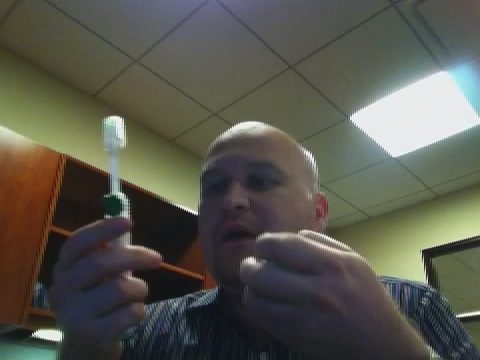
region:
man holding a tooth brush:
[96, 113, 137, 249]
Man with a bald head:
[197, 109, 324, 209]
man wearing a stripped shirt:
[148, 288, 446, 351]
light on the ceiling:
[342, 76, 478, 165]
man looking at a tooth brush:
[191, 160, 295, 199]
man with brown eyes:
[204, 175, 278, 188]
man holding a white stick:
[91, 189, 134, 285]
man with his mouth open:
[207, 219, 254, 249]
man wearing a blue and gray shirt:
[397, 281, 440, 325]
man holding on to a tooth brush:
[90, 103, 148, 275]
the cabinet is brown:
[7, 131, 109, 342]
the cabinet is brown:
[13, 121, 67, 323]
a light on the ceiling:
[322, 55, 473, 253]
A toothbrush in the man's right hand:
[103, 116, 137, 278]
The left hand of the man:
[245, 230, 431, 358]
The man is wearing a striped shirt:
[108, 277, 476, 359]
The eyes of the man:
[201, 175, 275, 190]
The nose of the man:
[224, 184, 248, 209]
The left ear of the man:
[310, 192, 329, 229]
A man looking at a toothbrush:
[49, 116, 475, 358]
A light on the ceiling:
[349, 70, 476, 157]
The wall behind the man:
[329, 184, 478, 344]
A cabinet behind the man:
[21, 159, 215, 327]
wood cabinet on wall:
[2, 127, 220, 333]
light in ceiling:
[352, 70, 476, 155]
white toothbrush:
[100, 118, 130, 277]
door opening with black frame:
[420, 234, 479, 358]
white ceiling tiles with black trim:
[2, 0, 478, 228]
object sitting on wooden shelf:
[31, 281, 50, 309]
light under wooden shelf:
[29, 326, 66, 343]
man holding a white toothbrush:
[47, 115, 477, 359]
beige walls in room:
[1, 52, 479, 290]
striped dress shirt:
[116, 275, 478, 355]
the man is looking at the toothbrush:
[64, 68, 304, 359]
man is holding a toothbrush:
[62, 96, 183, 337]